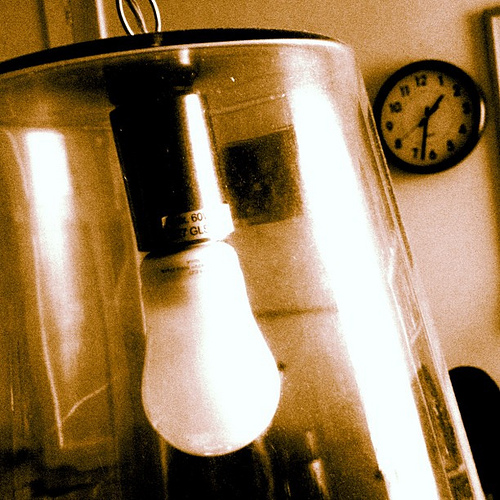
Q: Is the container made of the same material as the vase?
A: No, the container is made of glass and the vase is made of metal.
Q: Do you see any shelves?
A: No, there are no shelves.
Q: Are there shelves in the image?
A: No, there are no shelves.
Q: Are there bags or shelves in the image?
A: No, there are no shelves or bags.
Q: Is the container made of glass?
A: Yes, the container is made of glass.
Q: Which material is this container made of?
A: The container is made of glass.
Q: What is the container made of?
A: The container is made of glass.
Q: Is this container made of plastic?
A: No, the container is made of glass.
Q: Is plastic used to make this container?
A: No, the container is made of glass.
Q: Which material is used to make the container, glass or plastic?
A: The container is made of glass.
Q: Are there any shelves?
A: No, there are no shelves.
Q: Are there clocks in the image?
A: Yes, there is a clock.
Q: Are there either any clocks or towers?
A: Yes, there is a clock.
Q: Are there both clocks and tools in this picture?
A: No, there is a clock but no tools.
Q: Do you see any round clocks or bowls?
A: Yes, there is a round clock.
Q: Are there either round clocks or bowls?
A: Yes, there is a round clock.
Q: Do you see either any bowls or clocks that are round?
A: Yes, the clock is round.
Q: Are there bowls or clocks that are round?
A: Yes, the clock is round.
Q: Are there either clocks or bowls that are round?
A: Yes, the clock is round.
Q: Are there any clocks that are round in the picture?
A: Yes, there is a round clock.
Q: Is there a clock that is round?
A: Yes, there is a clock that is round.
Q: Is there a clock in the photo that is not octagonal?
A: Yes, there is an round clock.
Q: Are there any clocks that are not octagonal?
A: Yes, there is an round clock.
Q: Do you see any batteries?
A: No, there are no batteries.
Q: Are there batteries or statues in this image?
A: No, there are no batteries or statues.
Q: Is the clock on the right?
A: Yes, the clock is on the right of the image.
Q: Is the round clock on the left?
A: No, the clock is on the right of the image.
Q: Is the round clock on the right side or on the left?
A: The clock is on the right of the image.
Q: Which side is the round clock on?
A: The clock is on the right of the image.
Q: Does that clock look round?
A: Yes, the clock is round.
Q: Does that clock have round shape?
A: Yes, the clock is round.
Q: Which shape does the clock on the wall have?
A: The clock has round shape.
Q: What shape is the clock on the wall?
A: The clock is round.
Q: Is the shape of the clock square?
A: No, the clock is round.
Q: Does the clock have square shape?
A: No, the clock is round.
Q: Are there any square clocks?
A: No, there is a clock but it is round.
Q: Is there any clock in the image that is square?
A: No, there is a clock but it is round.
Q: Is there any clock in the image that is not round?
A: No, there is a clock but it is round.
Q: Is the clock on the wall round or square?
A: The clock is round.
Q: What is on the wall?
A: The clock is on the wall.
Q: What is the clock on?
A: The clock is on the wall.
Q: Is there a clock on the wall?
A: Yes, there is a clock on the wall.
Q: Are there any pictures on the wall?
A: No, there is a clock on the wall.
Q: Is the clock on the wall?
A: Yes, the clock is on the wall.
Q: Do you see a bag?
A: No, there are no bags.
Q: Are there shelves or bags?
A: No, there are no bags or shelves.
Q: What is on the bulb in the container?
A: The label is on the light bulb.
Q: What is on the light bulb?
A: The label is on the light bulb.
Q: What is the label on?
A: The label is on the light bulb.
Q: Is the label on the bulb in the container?
A: Yes, the label is on the light bulb.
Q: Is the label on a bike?
A: No, the label is on the light bulb.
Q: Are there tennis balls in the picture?
A: No, there are no tennis balls.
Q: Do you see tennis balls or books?
A: No, there are no tennis balls or books.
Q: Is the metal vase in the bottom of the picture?
A: Yes, the vase is in the bottom of the image.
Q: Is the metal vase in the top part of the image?
A: No, the vase is in the bottom of the image.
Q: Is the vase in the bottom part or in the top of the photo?
A: The vase is in the bottom of the image.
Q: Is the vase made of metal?
A: Yes, the vase is made of metal.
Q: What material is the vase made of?
A: The vase is made of metal.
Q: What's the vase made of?
A: The vase is made of metal.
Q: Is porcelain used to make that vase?
A: No, the vase is made of metal.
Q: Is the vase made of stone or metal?
A: The vase is made of metal.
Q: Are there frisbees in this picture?
A: No, there are no frisbees.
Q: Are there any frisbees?
A: No, there are no frisbees.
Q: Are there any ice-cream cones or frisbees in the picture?
A: No, there are no frisbees or ice-cream cones.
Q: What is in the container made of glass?
A: The bulb is in the container.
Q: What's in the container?
A: The bulb is in the container.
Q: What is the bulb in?
A: The bulb is in the container.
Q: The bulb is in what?
A: The bulb is in the container.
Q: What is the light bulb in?
A: The bulb is in the container.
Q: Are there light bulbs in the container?
A: Yes, there is a light bulb in the container.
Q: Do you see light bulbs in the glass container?
A: Yes, there is a light bulb in the container.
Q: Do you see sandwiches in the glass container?
A: No, there is a light bulb in the container.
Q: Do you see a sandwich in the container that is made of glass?
A: No, there is a light bulb in the container.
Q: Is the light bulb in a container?
A: Yes, the light bulb is in a container.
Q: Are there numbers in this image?
A: Yes, there are numbers.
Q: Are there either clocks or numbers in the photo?
A: Yes, there are numbers.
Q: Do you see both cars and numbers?
A: No, there are numbers but no cars.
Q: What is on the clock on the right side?
A: The numbers are on the clock.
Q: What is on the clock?
A: The numbers are on the clock.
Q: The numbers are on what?
A: The numbers are on the clock.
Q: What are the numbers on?
A: The numbers are on the clock.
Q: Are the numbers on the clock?
A: Yes, the numbers are on the clock.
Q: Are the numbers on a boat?
A: No, the numbers are on the clock.